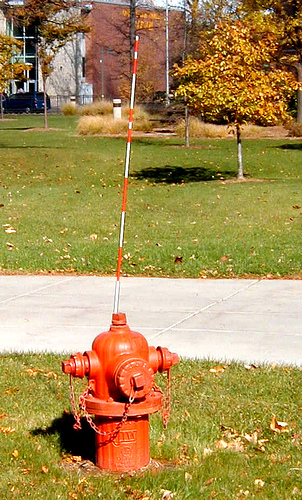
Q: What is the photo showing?
A: It is showing a lawn.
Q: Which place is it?
A: It is a lawn.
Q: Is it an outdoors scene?
A: Yes, it is outdoors.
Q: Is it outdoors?
A: Yes, it is outdoors.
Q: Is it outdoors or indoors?
A: It is outdoors.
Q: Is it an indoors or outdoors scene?
A: It is outdoors.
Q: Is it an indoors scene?
A: No, it is outdoors.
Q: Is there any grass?
A: Yes, there is grass.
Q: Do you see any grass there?
A: Yes, there is grass.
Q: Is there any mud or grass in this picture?
A: Yes, there is grass.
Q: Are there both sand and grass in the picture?
A: No, there is grass but no sand.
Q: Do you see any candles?
A: No, there are no candles.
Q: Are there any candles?
A: No, there are no candles.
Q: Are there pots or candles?
A: No, there are no candles or pots.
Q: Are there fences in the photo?
A: No, there are no fences.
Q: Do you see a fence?
A: No, there are no fences.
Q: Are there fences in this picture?
A: No, there are no fences.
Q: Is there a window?
A: Yes, there are windows.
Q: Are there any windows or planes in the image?
A: Yes, there are windows.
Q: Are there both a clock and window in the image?
A: No, there are windows but no clocks.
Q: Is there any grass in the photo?
A: Yes, there is grass.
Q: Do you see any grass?
A: Yes, there is grass.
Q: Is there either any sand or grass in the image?
A: Yes, there is grass.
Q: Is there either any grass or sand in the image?
A: Yes, there is grass.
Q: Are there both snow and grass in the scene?
A: No, there is grass but no snow.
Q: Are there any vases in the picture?
A: No, there are no vases.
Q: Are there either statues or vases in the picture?
A: No, there are no vases or statues.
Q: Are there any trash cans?
A: No, there are no trash cans.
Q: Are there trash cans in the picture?
A: No, there are no trash cans.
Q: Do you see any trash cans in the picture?
A: No, there are no trash cans.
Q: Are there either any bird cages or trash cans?
A: No, there are no trash cans or bird cages.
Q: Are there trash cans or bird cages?
A: No, there are no trash cans or bird cages.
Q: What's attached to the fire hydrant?
A: The chain is attached to the fire hydrant.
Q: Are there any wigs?
A: No, there are no wigs.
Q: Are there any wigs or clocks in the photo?
A: No, there are no wigs or clocks.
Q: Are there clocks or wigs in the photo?
A: No, there are no wigs or clocks.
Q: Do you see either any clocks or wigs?
A: No, there are no wigs or clocks.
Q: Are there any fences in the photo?
A: No, there are no fences.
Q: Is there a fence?
A: No, there are no fences.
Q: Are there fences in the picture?
A: No, there are no fences.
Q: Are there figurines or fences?
A: No, there are no fences or figurines.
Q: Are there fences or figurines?
A: No, there are no fences or figurines.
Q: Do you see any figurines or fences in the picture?
A: No, there are no fences or figurines.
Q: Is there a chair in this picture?
A: No, there are no chairs.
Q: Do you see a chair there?
A: No, there are no chairs.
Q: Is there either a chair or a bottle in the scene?
A: No, there are no chairs or bottles.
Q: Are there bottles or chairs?
A: No, there are no chairs or bottles.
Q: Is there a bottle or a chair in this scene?
A: No, there are no chairs or bottles.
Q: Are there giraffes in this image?
A: No, there are no giraffes.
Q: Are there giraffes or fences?
A: No, there are no giraffes or fences.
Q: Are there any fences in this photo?
A: No, there are no fences.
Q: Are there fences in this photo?
A: No, there are no fences.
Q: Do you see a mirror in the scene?
A: No, there are no mirrors.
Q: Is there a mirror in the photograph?
A: No, there are no mirrors.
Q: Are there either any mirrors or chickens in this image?
A: No, there are no mirrors or chickens.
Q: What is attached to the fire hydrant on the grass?
A: The chain is attached to the hydrant.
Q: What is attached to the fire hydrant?
A: The chain is attached to the hydrant.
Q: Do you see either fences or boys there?
A: No, there are no fences or boys.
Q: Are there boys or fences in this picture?
A: No, there are no fences or boys.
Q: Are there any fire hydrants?
A: Yes, there is a fire hydrant.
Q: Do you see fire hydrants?
A: Yes, there is a fire hydrant.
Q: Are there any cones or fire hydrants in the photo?
A: Yes, there is a fire hydrant.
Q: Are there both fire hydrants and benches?
A: No, there is a fire hydrant but no benches.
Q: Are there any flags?
A: No, there are no flags.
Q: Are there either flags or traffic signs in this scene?
A: No, there are no flags or traffic signs.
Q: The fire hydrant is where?
A: The fire hydrant is on the grass.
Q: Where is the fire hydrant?
A: The fire hydrant is on the grass.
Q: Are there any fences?
A: No, there are no fences.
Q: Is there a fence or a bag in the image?
A: No, there are no fences or bags.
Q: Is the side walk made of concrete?
A: Yes, the side walk is made of concrete.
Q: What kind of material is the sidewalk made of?
A: The sidewalk is made of cement.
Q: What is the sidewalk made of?
A: The sidewalk is made of concrete.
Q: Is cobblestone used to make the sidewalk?
A: No, the sidewalk is made of concrete.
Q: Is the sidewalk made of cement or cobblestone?
A: The sidewalk is made of cement.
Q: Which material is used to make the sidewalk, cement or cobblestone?
A: The sidewalk is made of cement.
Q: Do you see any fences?
A: No, there are no fences.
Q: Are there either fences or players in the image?
A: No, there are no fences or players.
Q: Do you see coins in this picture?
A: No, there are no coins.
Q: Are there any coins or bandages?
A: No, there are no coins or bandages.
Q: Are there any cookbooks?
A: No, there are no cookbooks.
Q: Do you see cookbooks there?
A: No, there are no cookbooks.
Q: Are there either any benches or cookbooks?
A: No, there are no cookbooks or benches.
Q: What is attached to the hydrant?
A: The chain is attached to the hydrant.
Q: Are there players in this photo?
A: No, there are no players.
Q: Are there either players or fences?
A: No, there are no players or fences.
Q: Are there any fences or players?
A: No, there are no players or fences.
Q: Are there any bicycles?
A: No, there are no bicycles.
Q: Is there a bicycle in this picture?
A: No, there are no bicycles.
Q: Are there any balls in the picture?
A: No, there are no balls.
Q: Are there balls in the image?
A: No, there are no balls.